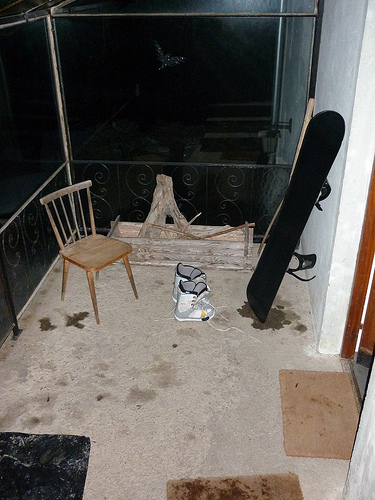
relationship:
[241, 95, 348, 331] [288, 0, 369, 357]
snowboard leaning against wall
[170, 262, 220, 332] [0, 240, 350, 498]
snow boots on floor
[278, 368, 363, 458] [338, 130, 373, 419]
mat in front of door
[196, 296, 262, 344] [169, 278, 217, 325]
laces on snowboard boots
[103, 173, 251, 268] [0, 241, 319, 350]
wood on porch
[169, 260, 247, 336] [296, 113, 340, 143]
snowboard boots on ground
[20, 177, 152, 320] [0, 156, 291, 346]
chair by railing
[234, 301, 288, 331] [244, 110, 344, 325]
spot under snowboard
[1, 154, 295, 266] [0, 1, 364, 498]
railing around porch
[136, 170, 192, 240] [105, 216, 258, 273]
wood in container